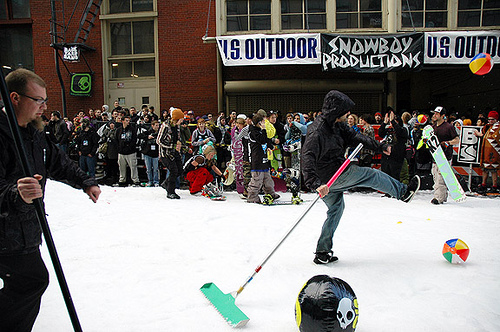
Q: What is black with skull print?
A: The ball.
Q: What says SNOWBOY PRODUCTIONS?
A: The sign.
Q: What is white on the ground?
A: The snow.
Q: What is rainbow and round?
A: Beach balls.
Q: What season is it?
A: Winter.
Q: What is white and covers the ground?
A: Snow.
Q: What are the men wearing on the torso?
A: A jacket.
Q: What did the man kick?
A: A beach ball.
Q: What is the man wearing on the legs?
A: Pants.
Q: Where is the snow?
A: On the ground.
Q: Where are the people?
A: On the side.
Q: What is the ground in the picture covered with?
A: Snow.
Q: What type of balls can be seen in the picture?
A: Beach balls.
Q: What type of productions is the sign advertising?
A: Snowboy.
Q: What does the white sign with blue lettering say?
A: U.S. Outdoor.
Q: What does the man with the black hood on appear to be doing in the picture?
A: Kicking the ball.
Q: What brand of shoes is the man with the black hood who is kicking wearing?
A: Nike.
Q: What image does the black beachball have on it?
A: A skull.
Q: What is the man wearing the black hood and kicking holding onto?
A: A shovel.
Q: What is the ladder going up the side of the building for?
A: A fire escape.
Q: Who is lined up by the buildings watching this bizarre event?
A: A crowd of people.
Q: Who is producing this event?
A: Snowboy Productions.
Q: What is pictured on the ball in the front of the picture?
A: A skull.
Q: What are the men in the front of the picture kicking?
A: Beach Balls.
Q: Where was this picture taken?
A: On a street.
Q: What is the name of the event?
A: U.S. Outdoor.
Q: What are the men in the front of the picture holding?
A: Snow sweepers.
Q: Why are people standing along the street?
A: To watch the parade.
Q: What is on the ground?
A: Snow.